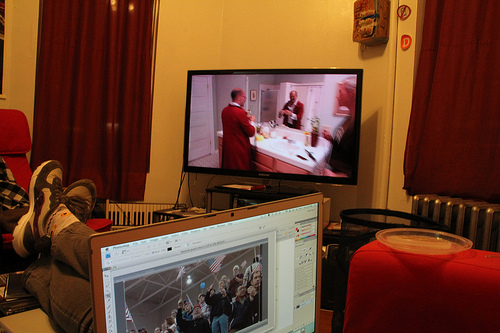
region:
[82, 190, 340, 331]
a laptop with a photo-editing program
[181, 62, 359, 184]
a television with Arrested Development on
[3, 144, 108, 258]
feet resting on a chair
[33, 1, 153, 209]
long dark red curtains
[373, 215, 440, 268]
an empty glass plate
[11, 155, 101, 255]
gray sneakers on feet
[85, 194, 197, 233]
an electric keyboard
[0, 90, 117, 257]
a red chair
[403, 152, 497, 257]
a radiator under a window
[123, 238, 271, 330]
people in a gymnasium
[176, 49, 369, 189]
television turned on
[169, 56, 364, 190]
television displaying a tv program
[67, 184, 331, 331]
laptop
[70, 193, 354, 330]
laptop screen opened and turned on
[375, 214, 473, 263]
clear ashtray sitting on the edge of a red couch carm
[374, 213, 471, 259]
clear empty ashtray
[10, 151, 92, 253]
pair of tennis shoes being worn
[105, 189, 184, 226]
piano type keyboard turned upside down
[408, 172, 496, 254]
silver radiator heater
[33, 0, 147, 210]
dark red curtain hanging on the window to the left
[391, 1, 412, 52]
Two round stickers stuck to a wall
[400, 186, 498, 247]
A wall heater under a window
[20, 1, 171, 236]
Dark red curtains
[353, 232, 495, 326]
The arm of a red couch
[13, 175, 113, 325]
A man's feet crossed at the ankles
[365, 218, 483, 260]
A plastic lid sitting on the arm of a couch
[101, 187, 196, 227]
A black and white keyboard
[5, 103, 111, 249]
A red chair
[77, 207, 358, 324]
An open and in use laptop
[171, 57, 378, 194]
A bathroom scene visible in a television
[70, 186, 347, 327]
The computer is being used.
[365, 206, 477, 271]
A plastic lid.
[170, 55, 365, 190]
A large television.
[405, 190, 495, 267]
A radiator.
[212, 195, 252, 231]
A small webcam is in the computer screen.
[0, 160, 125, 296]
The person is wearing shoes.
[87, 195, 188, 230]
A keyboard is on the ground.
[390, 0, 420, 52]
Stickers are on the wall.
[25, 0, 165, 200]
A curtain is covering the window.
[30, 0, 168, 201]
The curtain is a dark red color.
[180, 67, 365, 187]
a television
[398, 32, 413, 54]
the letter D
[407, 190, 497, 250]
a silver radiator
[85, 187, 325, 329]
the monitor of a laptop computer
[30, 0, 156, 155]
a red curtain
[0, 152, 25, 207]
black and white fabric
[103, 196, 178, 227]
a musical keyboard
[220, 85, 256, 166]
a man on the television screen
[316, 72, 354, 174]
a woman on the television screen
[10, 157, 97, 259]
sneakers with grey laces